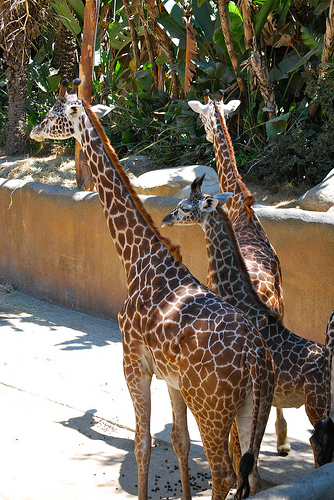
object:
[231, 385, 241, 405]
spot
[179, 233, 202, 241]
wall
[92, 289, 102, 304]
wall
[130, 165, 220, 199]
rock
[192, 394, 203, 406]
spot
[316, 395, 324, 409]
spot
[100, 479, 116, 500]
ground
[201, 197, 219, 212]
ears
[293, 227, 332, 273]
wall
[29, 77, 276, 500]
giraffe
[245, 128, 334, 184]
bush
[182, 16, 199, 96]
dead leaf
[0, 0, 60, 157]
tree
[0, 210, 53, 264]
wall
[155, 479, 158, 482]
stone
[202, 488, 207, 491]
stone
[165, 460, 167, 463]
stone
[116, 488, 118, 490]
stone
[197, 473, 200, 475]
stone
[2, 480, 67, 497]
ground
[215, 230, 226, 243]
spot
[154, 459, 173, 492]
rocks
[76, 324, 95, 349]
ground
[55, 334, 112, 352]
shadow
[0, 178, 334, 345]
cement wall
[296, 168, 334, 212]
rock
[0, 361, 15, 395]
ground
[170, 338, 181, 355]
spot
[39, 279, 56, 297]
wall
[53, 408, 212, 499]
shadow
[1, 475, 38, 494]
ground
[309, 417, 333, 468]
hair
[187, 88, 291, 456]
giraffe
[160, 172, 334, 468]
giraffe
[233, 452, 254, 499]
hair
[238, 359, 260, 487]
tail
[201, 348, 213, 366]
spot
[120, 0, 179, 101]
trees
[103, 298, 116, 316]
wall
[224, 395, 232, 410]
spot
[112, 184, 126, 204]
spot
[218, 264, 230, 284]
spot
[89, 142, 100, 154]
spot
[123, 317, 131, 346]
spot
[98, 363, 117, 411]
ground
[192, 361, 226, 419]
pattern